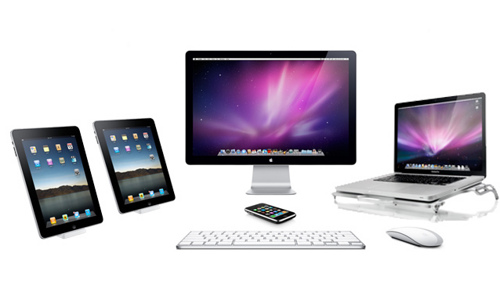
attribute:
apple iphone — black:
[243, 201, 297, 225]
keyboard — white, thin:
[176, 228, 365, 253]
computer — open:
[333, 92, 493, 213]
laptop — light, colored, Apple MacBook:
[332, 90, 499, 222]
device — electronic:
[176, 225, 366, 253]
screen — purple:
[392, 94, 485, 174]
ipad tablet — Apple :
[93, 119, 180, 213]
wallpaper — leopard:
[396, 97, 483, 172]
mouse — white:
[385, 226, 445, 247]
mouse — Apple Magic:
[375, 220, 448, 254]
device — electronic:
[10, 126, 102, 238]